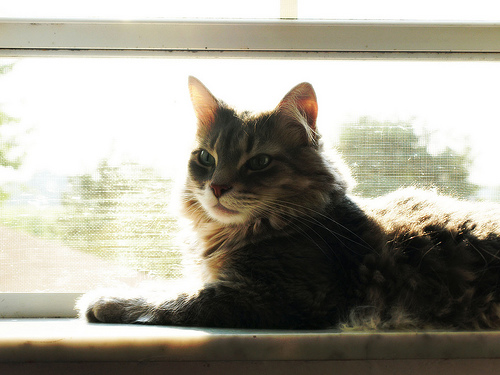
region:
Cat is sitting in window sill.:
[123, 83, 481, 358]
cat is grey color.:
[211, 164, 448, 305]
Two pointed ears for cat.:
[165, 59, 353, 139]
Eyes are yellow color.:
[194, 137, 296, 189]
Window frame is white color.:
[9, 4, 443, 138]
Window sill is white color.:
[33, 313, 393, 367]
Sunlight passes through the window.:
[10, 32, 470, 324]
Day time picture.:
[23, 7, 476, 352]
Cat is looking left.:
[164, 90, 301, 227]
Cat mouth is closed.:
[183, 133, 284, 243]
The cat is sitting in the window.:
[76, 76, 498, 334]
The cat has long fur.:
[76, 73, 499, 333]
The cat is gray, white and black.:
[82, 74, 499, 328]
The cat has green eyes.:
[193, 141, 278, 176]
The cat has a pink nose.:
[205, 180, 232, 198]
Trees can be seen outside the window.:
[1, 55, 498, 292]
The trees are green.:
[0, 56, 499, 291]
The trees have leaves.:
[0, 55, 499, 291]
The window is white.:
[0, 17, 499, 317]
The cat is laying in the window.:
[77, 69, 498, 331]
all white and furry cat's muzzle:
[200, 183, 240, 225]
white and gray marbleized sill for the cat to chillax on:
[0, 317, 499, 373]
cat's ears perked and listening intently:
[187, 74, 318, 128]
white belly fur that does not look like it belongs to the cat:
[338, 305, 413, 332]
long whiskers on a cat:
[235, 195, 377, 257]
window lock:
[275, 0, 300, 21]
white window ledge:
[0, 17, 499, 63]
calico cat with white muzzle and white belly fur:
[85, 74, 498, 329]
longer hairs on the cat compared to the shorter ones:
[357, 184, 498, 328]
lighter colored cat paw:
[81, 295, 141, 325]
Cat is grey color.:
[161, 96, 483, 320]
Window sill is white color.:
[40, 300, 205, 365]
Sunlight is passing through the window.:
[15, 30, 441, 291]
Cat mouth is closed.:
[176, 169, 262, 231]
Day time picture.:
[36, 28, 462, 323]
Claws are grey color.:
[65, 288, 134, 345]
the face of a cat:
[148, 33, 379, 297]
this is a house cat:
[104, 29, 392, 359]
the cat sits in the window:
[32, 29, 474, 356]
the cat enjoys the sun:
[28, 33, 442, 373]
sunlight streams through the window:
[157, 52, 418, 260]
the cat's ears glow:
[68, 53, 403, 307]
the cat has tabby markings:
[121, 59, 336, 310]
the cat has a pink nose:
[112, 58, 374, 282]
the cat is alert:
[61, 56, 482, 357]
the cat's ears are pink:
[102, 48, 453, 326]